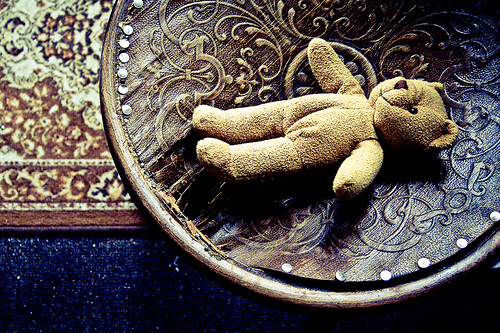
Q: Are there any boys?
A: No, there are no boys.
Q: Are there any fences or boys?
A: No, there are no boys or fences.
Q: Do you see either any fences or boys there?
A: No, there are no boys or fences.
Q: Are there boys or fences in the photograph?
A: No, there are no boys or fences.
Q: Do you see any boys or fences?
A: No, there are no boys or fences.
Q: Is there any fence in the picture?
A: No, there are no fences.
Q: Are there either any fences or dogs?
A: No, there are no fences or dogs.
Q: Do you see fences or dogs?
A: No, there are no fences or dogs.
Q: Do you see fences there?
A: No, there are no fences.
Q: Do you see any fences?
A: No, there are no fences.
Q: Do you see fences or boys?
A: No, there are no fences or boys.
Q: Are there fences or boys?
A: No, there are no fences or boys.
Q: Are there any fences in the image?
A: No, there are no fences.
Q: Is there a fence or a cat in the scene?
A: No, there are no fences or cats.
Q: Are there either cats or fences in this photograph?
A: No, there are no fences or cats.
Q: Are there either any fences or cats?
A: No, there are no fences or cats.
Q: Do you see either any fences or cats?
A: No, there are no fences or cats.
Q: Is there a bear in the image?
A: Yes, there is a bear.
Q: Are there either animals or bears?
A: Yes, there is a bear.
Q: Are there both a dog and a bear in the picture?
A: No, there is a bear but no dogs.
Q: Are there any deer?
A: No, there are no deer.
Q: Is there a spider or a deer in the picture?
A: No, there are no deer or spiders.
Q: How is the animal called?
A: The animal is a bear.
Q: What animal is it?
A: The animal is a bear.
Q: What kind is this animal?
A: This is a bear.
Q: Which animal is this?
A: This is a bear.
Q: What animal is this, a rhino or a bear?
A: This is a bear.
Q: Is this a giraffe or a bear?
A: This is a bear.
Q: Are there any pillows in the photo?
A: No, there are no pillows.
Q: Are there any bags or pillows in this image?
A: No, there are no pillows or bags.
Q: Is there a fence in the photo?
A: No, there are no fences.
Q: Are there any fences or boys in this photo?
A: No, there are no fences or boys.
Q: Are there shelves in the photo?
A: No, there are no shelves.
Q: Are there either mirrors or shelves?
A: No, there are no shelves or mirrors.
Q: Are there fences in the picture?
A: No, there are no fences.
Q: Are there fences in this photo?
A: No, there are no fences.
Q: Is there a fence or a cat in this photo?
A: No, there are no fences or cats.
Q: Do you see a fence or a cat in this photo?
A: No, there are no fences or cats.